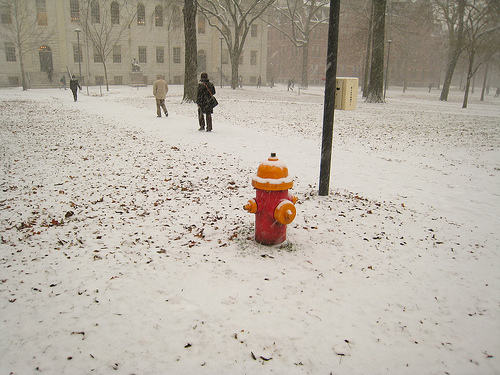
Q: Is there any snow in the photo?
A: Yes, there is snow.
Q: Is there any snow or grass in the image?
A: Yes, there is snow.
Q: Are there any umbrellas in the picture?
A: No, there are no umbrellas.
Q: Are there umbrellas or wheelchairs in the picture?
A: No, there are no umbrellas or wheelchairs.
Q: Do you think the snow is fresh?
A: Yes, the snow is fresh.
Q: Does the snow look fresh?
A: Yes, the snow is fresh.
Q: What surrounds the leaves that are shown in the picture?
A: The snow surrounds the leaves.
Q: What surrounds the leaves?
A: The snow surrounds the leaves.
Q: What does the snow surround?
A: The snow surrounds the leaves.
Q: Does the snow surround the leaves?
A: Yes, the snow surrounds the leaves.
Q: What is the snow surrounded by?
A: The snow is surrounded by the leaves.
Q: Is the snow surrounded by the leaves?
A: Yes, the snow is surrounded by the leaves.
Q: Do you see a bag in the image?
A: Yes, there is a bag.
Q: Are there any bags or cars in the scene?
A: Yes, there is a bag.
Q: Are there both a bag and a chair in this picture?
A: No, there is a bag but no chairs.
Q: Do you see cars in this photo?
A: No, there are no cars.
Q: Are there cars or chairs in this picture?
A: No, there are no cars or chairs.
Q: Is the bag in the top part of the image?
A: Yes, the bag is in the top of the image.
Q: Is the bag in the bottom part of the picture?
A: No, the bag is in the top of the image.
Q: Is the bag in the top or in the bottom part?
A: The bag is in the top of the image.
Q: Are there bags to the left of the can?
A: Yes, there is a bag to the left of the can.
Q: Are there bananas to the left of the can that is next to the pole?
A: No, there is a bag to the left of the can.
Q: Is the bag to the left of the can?
A: Yes, the bag is to the left of the can.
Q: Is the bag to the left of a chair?
A: No, the bag is to the left of the can.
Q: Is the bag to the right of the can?
A: No, the bag is to the left of the can.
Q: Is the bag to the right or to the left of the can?
A: The bag is to the left of the can.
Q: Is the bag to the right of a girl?
A: No, the bag is to the right of a man.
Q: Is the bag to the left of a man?
A: Yes, the bag is to the left of a man.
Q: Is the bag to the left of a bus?
A: No, the bag is to the left of a man.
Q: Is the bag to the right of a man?
A: No, the bag is to the left of a man.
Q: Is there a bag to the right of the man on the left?
A: Yes, there is a bag to the right of the man.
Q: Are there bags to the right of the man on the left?
A: Yes, there is a bag to the right of the man.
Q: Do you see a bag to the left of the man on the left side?
A: No, the bag is to the right of the man.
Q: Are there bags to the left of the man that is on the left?
A: No, the bag is to the right of the man.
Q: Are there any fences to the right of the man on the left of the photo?
A: No, there is a bag to the right of the man.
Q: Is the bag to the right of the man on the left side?
A: Yes, the bag is to the right of the man.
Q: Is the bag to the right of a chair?
A: No, the bag is to the right of the man.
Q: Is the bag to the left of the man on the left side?
A: No, the bag is to the right of the man.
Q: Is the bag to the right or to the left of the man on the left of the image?
A: The bag is to the right of the man.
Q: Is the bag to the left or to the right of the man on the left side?
A: The bag is to the right of the man.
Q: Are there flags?
A: No, there are no flags.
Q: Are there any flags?
A: No, there are no flags.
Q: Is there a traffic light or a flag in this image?
A: No, there are no flags or traffic lights.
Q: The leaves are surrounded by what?
A: The leaves are surrounded by the snow.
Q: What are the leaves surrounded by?
A: The leaves are surrounded by the snow.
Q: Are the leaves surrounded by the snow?
A: Yes, the leaves are surrounded by the snow.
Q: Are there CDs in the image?
A: No, there are no cds.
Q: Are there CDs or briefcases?
A: No, there are no CDs or briefcases.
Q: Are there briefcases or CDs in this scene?
A: No, there are no CDs or briefcases.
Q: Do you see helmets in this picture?
A: No, there are no helmets.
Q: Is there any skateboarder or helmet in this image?
A: No, there are no helmets or skateboarders.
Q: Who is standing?
A: The man is standing.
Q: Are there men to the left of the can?
A: Yes, there is a man to the left of the can.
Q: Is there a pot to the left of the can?
A: No, there is a man to the left of the can.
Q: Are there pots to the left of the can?
A: No, there is a man to the left of the can.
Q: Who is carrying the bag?
A: The man is carrying the bag.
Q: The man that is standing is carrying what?
A: The man is carrying a bag.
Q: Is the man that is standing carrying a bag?
A: Yes, the man is carrying a bag.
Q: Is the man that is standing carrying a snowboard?
A: No, the man is carrying a bag.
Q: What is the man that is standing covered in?
A: The man is covered in snow.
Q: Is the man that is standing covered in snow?
A: Yes, the man is covered in snow.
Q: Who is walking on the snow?
A: The man is walking on the snow.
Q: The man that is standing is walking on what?
A: The man is walking on the snow.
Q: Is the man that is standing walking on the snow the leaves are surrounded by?
A: Yes, the man is walking on the snow.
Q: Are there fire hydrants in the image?
A: Yes, there is a fire hydrant.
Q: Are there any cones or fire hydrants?
A: Yes, there is a fire hydrant.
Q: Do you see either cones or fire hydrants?
A: Yes, there is a fire hydrant.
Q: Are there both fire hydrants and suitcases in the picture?
A: No, there is a fire hydrant but no suitcases.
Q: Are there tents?
A: No, there are no tents.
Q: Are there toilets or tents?
A: No, there are no tents or toilets.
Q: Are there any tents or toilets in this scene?
A: No, there are no tents or toilets.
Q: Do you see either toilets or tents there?
A: No, there are no tents or toilets.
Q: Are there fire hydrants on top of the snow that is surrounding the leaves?
A: Yes, there is a fire hydrant on top of the snow.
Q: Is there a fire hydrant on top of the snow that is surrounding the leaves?
A: Yes, there is a fire hydrant on top of the snow.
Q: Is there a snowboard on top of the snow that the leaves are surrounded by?
A: No, there is a fire hydrant on top of the snow.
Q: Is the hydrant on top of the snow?
A: Yes, the hydrant is on top of the snow.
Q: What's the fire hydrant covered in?
A: The fire hydrant is covered in snow.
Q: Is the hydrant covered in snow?
A: Yes, the hydrant is covered in snow.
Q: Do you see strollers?
A: No, there are no strollers.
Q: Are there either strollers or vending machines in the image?
A: No, there are no strollers or vending machines.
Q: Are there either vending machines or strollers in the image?
A: No, there are no strollers or vending machines.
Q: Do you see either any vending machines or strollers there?
A: No, there are no strollers or vending machines.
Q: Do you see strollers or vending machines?
A: No, there are no strollers or vending machines.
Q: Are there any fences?
A: No, there are no fences.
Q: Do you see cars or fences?
A: No, there are no fences or cars.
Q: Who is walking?
A: The man is walking.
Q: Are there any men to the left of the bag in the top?
A: Yes, there is a man to the left of the bag.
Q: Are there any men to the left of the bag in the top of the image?
A: Yes, there is a man to the left of the bag.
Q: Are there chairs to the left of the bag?
A: No, there is a man to the left of the bag.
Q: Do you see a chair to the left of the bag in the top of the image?
A: No, there is a man to the left of the bag.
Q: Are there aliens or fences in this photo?
A: No, there are no fences or aliens.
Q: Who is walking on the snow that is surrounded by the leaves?
A: The man is walking on the snow.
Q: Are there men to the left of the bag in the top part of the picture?
A: Yes, there is a man to the left of the bag.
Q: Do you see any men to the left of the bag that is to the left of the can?
A: Yes, there is a man to the left of the bag.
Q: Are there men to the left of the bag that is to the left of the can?
A: Yes, there is a man to the left of the bag.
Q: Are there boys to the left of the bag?
A: No, there is a man to the left of the bag.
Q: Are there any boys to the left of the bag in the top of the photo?
A: No, there is a man to the left of the bag.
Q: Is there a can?
A: Yes, there is a can.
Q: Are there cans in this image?
A: Yes, there is a can.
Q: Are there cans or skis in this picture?
A: Yes, there is a can.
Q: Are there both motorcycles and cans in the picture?
A: No, there is a can but no motorcycles.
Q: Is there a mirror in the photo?
A: No, there are no mirrors.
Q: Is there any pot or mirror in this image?
A: No, there are no mirrors or pots.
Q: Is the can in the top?
A: Yes, the can is in the top of the image.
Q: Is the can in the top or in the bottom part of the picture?
A: The can is in the top of the image.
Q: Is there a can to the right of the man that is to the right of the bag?
A: Yes, there is a can to the right of the man.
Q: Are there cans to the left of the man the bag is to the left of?
A: No, the can is to the right of the man.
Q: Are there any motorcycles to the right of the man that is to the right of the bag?
A: No, there is a can to the right of the man.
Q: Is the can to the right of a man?
A: Yes, the can is to the right of a man.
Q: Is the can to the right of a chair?
A: No, the can is to the right of a man.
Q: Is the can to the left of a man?
A: No, the can is to the right of a man.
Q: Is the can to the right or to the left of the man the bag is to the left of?
A: The can is to the right of the man.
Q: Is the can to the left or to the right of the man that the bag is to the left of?
A: The can is to the right of the man.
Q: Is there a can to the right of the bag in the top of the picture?
A: Yes, there is a can to the right of the bag.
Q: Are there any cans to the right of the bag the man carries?
A: Yes, there is a can to the right of the bag.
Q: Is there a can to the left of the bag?
A: No, the can is to the right of the bag.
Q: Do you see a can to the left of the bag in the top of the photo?
A: No, the can is to the right of the bag.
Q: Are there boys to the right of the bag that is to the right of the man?
A: No, there is a can to the right of the bag.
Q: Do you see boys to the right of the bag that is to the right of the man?
A: No, there is a can to the right of the bag.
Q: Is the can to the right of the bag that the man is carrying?
A: Yes, the can is to the right of the bag.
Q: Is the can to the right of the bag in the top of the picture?
A: Yes, the can is to the right of the bag.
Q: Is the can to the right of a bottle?
A: No, the can is to the right of the bag.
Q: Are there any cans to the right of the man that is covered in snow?
A: Yes, there is a can to the right of the man.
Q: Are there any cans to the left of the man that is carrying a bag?
A: No, the can is to the right of the man.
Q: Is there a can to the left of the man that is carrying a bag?
A: No, the can is to the right of the man.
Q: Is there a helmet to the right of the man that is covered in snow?
A: No, there is a can to the right of the man.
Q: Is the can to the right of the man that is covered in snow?
A: Yes, the can is to the right of the man.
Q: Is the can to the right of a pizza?
A: No, the can is to the right of the man.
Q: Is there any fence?
A: No, there are no fences.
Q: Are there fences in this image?
A: No, there are no fences.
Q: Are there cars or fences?
A: No, there are no fences or cars.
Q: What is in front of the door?
A: The steps are in front of the door.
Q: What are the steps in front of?
A: The steps are in front of the door.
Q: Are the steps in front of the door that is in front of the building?
A: Yes, the steps are in front of the door.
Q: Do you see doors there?
A: Yes, there is a door.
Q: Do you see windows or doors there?
A: Yes, there is a door.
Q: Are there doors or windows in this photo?
A: Yes, there is a door.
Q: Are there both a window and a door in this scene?
A: Yes, there are both a door and a window.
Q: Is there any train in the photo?
A: No, there are no trains.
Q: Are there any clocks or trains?
A: No, there are no trains or clocks.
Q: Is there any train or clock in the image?
A: No, there are no trains or clocks.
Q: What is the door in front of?
A: The door is in front of the building.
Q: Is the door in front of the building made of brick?
A: Yes, the door is in front of the building.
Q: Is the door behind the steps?
A: Yes, the door is behind the steps.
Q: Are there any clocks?
A: No, there are no clocks.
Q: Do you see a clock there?
A: No, there are no clocks.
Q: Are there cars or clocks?
A: No, there are no clocks or cars.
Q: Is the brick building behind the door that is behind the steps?
A: Yes, the building is behind the door.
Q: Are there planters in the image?
A: No, there are no planters.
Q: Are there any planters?
A: No, there are no planters.